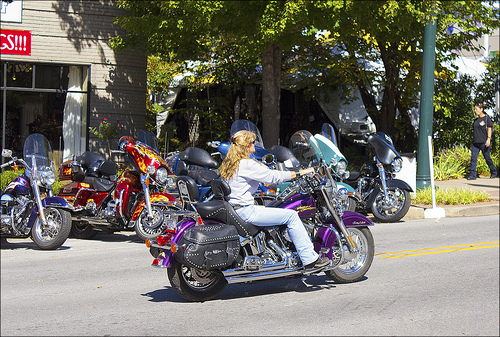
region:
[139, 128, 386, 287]
woman on a motorcycle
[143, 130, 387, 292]
woman on a purple motorcycle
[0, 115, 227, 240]
motorcycles parked on the side of the road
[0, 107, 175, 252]
motorcycles parked in front of a bush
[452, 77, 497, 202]
woman walking on the sidewalk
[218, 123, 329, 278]
woman in white sitting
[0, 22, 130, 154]
a store front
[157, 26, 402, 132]
a tent under a tree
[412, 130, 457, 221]
a pole on the street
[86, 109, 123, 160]
a red rose bush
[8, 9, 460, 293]
a female motorcycle rider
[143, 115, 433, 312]
the lady is riding her motorcycle on the street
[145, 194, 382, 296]
the bike is purple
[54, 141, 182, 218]
this motocycle is red and yellow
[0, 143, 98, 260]
this motorcycle is gren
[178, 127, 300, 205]
this motorcycle is blue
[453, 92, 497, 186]
this person is walking through the area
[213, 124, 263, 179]
the lady has a pony tail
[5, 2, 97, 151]
this is a building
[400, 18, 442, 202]
this is a pole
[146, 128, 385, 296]
the woman is on a purple motorcycle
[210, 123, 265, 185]
the womans hair is red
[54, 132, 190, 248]
this motorcycle is red and yellow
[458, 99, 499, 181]
a woman is walking down the street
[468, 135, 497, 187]
the woman is wearing blue jeans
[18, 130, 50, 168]
the windshield is attached at the front of the bike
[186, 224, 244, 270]
the saddle bag is black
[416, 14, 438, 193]
the pole by the sidewalk is green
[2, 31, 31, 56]
the sign is red with white writing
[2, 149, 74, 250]
this motorcycle is blue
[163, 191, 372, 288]
purple metallic motor bike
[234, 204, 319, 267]
white wash denim jeans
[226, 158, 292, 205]
grey cotton sweat shirt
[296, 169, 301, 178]
black watch on wrist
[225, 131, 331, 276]
woman riding motorcycle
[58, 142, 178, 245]
orange and red motorcycle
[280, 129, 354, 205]
blue and white motorcycle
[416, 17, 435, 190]
green painted metal lamp post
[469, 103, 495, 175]
girl walking on sidewalk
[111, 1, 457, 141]
tree with green leaves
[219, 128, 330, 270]
blonde hair lady riding motorcycle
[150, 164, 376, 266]
a purple motorcycle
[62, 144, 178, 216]
a red motorcycle with flame decal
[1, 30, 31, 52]
a red sign with white writing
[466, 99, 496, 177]
person in black short sleeve shirt walking on sidewalk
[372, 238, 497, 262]
double yellow line in street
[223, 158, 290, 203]
white long sleeve shirt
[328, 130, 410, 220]
a black motorcycle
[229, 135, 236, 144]
a lady hair clip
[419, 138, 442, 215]
a white pole with square bottom